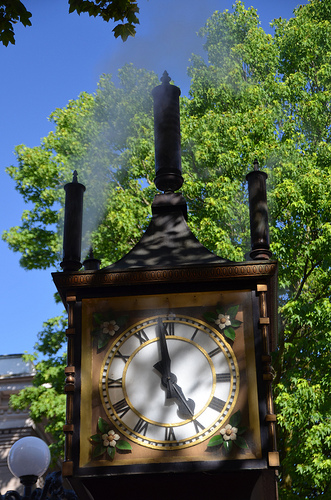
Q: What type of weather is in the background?
A: It is clear.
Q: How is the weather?
A: It is clear.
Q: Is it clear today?
A: Yes, it is clear.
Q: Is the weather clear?
A: Yes, it is clear.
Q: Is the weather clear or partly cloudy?
A: It is clear.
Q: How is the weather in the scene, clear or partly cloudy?
A: It is clear.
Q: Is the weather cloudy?
A: No, it is clear.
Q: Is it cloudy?
A: No, it is clear.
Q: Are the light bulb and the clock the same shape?
A: No, the light bulb is round and the clock is square.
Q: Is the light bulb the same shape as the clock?
A: No, the light bulb is round and the clock is square.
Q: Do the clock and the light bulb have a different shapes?
A: Yes, the clock is round and the light bulb is square.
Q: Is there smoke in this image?
A: Yes, there is smoke.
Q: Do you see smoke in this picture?
A: Yes, there is smoke.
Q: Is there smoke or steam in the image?
A: Yes, there is smoke.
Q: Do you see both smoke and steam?
A: Yes, there are both smoke and steam.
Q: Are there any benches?
A: No, there are no benches.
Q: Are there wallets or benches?
A: No, there are no benches or wallets.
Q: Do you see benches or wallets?
A: No, there are no benches or wallets.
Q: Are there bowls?
A: No, there are no bowls.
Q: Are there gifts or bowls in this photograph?
A: No, there are no bowls or gifts.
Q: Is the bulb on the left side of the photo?
A: Yes, the bulb is on the left of the image.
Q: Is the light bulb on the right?
A: No, the light bulb is on the left of the image.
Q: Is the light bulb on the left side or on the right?
A: The light bulb is on the left of the image.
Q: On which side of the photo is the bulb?
A: The bulb is on the left of the image.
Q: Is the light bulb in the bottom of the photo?
A: Yes, the light bulb is in the bottom of the image.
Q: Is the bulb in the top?
A: No, the bulb is in the bottom of the image.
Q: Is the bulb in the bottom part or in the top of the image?
A: The bulb is in the bottom of the image.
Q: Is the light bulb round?
A: Yes, the light bulb is round.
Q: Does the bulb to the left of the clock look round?
A: Yes, the light bulb is round.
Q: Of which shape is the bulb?
A: The bulb is round.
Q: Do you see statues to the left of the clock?
A: No, there is a light bulb to the left of the clock.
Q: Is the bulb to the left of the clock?
A: Yes, the bulb is to the left of the clock.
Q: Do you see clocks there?
A: Yes, there is a clock.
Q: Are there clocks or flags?
A: Yes, there is a clock.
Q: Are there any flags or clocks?
A: Yes, there is a clock.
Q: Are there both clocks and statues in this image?
A: No, there is a clock but no statues.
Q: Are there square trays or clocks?
A: Yes, there is a square clock.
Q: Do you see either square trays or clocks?
A: Yes, there is a square clock.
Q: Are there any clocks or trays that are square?
A: Yes, the clock is square.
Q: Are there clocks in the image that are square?
A: Yes, there is a square clock.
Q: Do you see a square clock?
A: Yes, there is a square clock.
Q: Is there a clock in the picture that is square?
A: Yes, there is a clock that is square.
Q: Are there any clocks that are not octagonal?
A: Yes, there is an square clock.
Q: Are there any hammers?
A: No, there are no hammers.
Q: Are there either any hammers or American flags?
A: No, there are no hammers or American flags.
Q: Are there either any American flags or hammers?
A: No, there are no hammers or American flags.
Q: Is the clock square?
A: Yes, the clock is square.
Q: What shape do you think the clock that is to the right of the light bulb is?
A: The clock is square.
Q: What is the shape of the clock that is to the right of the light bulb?
A: The clock is square.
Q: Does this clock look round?
A: No, the clock is square.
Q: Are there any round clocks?
A: No, there is a clock but it is square.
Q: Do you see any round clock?
A: No, there is a clock but it is square.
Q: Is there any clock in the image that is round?
A: No, there is a clock but it is square.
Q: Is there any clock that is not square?
A: No, there is a clock but it is square.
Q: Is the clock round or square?
A: The clock is square.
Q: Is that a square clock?
A: Yes, that is a square clock.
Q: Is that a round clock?
A: No, that is a square clock.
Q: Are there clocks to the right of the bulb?
A: Yes, there is a clock to the right of the bulb.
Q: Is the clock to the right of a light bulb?
A: Yes, the clock is to the right of a light bulb.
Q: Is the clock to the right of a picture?
A: No, the clock is to the right of a light bulb.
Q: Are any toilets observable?
A: No, there are no toilets.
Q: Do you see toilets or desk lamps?
A: No, there are no toilets or desk lamps.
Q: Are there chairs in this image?
A: No, there are no chairs.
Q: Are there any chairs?
A: No, there are no chairs.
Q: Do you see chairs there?
A: No, there are no chairs.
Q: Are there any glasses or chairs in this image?
A: No, there are no chairs or glasses.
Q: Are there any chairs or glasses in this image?
A: No, there are no chairs or glasses.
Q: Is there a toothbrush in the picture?
A: No, there are no toothbrushes.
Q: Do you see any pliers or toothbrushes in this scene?
A: No, there are no toothbrushes or pliers.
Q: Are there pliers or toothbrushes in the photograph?
A: No, there are no toothbrushes or pliers.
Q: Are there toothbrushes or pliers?
A: No, there are no toothbrushes or pliers.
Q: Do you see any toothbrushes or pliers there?
A: No, there are no toothbrushes or pliers.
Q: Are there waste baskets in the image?
A: No, there are no waste baskets.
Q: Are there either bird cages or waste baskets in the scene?
A: No, there are no waste baskets or bird cages.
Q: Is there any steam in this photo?
A: Yes, there is steam.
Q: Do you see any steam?
A: Yes, there is steam.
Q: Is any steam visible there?
A: Yes, there is steam.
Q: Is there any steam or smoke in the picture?
A: Yes, there is steam.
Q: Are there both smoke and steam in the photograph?
A: Yes, there are both steam and smoke.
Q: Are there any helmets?
A: No, there are no helmets.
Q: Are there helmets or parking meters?
A: No, there are no helmets or parking meters.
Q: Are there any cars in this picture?
A: No, there are no cars.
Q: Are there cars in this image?
A: No, there are no cars.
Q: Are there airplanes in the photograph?
A: No, there are no airplanes.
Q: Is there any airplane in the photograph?
A: No, there are no airplanes.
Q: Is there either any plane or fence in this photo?
A: No, there are no airplanes or fences.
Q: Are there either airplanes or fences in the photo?
A: No, there are no airplanes or fences.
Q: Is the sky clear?
A: Yes, the sky is clear.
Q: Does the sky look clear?
A: Yes, the sky is clear.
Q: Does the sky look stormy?
A: No, the sky is clear.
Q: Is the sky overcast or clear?
A: The sky is clear.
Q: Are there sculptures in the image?
A: No, there are no sculptures.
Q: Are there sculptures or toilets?
A: No, there are no sculptures or toilets.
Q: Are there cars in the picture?
A: No, there are no cars.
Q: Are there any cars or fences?
A: No, there are no cars or fences.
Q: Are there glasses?
A: No, there are no glasses.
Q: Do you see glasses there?
A: No, there are no glasses.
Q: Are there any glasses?
A: No, there are no glasses.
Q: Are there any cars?
A: No, there are no cars.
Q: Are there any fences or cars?
A: No, there are no cars or fences.